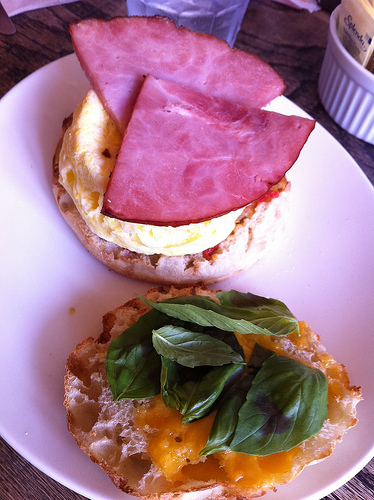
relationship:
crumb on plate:
[26, 424, 38, 443] [10, 423, 34, 442]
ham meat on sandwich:
[65, 14, 317, 226] [35, 11, 368, 498]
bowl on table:
[318, 0, 374, 143] [228, 412, 373, 498]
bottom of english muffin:
[63, 69, 263, 278] [47, 17, 316, 290]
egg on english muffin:
[61, 88, 116, 232] [47, 17, 316, 290]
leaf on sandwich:
[150, 323, 248, 367] [63, 284, 362, 497]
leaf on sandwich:
[150, 324, 248, 370] [49, 15, 311, 284]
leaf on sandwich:
[133, 283, 300, 340] [35, 11, 368, 498]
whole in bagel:
[116, 449, 152, 488] [62, 283, 362, 498]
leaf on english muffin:
[150, 323, 248, 367] [63, 281, 364, 498]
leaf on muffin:
[133, 283, 300, 340] [62, 290, 356, 496]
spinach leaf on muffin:
[99, 308, 167, 398] [62, 290, 356, 496]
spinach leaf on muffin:
[158, 371, 240, 430] [62, 290, 356, 496]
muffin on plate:
[62, 290, 356, 496] [0, 49, 373, 497]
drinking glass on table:
[123, 1, 248, 43] [1, 1, 372, 498]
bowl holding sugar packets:
[314, 4, 373, 148] [336, 1, 373, 62]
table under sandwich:
[1, 1, 372, 498] [42, 10, 325, 287]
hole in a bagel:
[73, 403, 96, 427] [62, 283, 362, 498]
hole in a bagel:
[67, 348, 103, 387] [62, 283, 362, 498]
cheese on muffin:
[127, 314, 326, 496] [62, 290, 356, 496]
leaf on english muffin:
[137, 291, 303, 340] [63, 281, 364, 498]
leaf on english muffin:
[223, 353, 333, 455] [63, 281, 364, 498]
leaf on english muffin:
[133, 283, 300, 340] [63, 281, 364, 498]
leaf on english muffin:
[155, 352, 249, 425] [63, 281, 364, 498]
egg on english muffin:
[54, 89, 245, 254] [47, 17, 316, 290]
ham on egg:
[68, 16, 294, 133] [54, 89, 245, 254]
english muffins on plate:
[58, 68, 317, 492] [0, 49, 373, 497]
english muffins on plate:
[58, 285, 364, 493] [0, 49, 373, 497]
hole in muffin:
[73, 403, 96, 427] [62, 290, 356, 496]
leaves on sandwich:
[103, 287, 330, 456] [63, 284, 362, 497]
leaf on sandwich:
[105, 301, 195, 406] [49, 15, 311, 284]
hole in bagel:
[73, 403, 96, 427] [62, 283, 362, 498]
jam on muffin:
[145, 410, 180, 452] [62, 290, 356, 496]